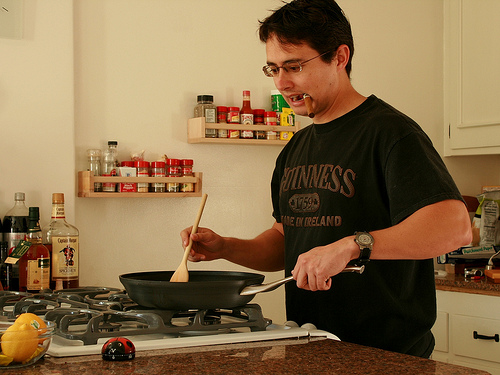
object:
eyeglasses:
[262, 46, 338, 77]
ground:
[466, 129, 499, 156]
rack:
[78, 170, 204, 197]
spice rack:
[186, 117, 301, 144]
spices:
[181, 158, 195, 192]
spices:
[240, 90, 254, 139]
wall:
[444, 0, 498, 82]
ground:
[452, 160, 471, 173]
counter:
[0, 281, 5, 291]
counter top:
[260, 338, 350, 375]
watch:
[354, 229, 375, 266]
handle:
[239, 265, 365, 296]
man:
[180, 0, 473, 359]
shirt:
[270, 94, 469, 360]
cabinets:
[443, 0, 499, 158]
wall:
[100, 83, 174, 121]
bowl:
[0, 313, 53, 368]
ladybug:
[101, 336, 136, 361]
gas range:
[283, 321, 317, 332]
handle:
[473, 330, 499, 342]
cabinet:
[431, 312, 500, 364]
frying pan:
[118, 265, 365, 311]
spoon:
[169, 193, 208, 282]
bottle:
[41, 193, 79, 290]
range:
[42, 293, 340, 364]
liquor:
[42, 192, 78, 290]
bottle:
[3, 192, 30, 293]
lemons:
[0, 312, 52, 367]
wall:
[0, 43, 54, 84]